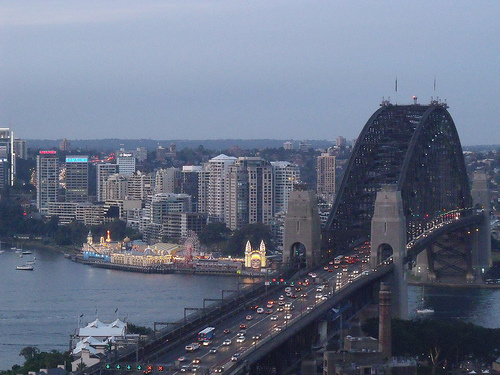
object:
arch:
[325, 95, 471, 262]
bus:
[197, 327, 215, 342]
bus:
[334, 255, 343, 264]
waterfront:
[83, 229, 267, 270]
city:
[0, 0, 500, 375]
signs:
[40, 150, 89, 163]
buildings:
[10, 130, 278, 244]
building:
[245, 240, 267, 269]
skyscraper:
[224, 156, 275, 231]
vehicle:
[270, 314, 278, 320]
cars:
[177, 237, 371, 373]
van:
[283, 302, 294, 313]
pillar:
[370, 187, 408, 277]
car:
[209, 348, 217, 352]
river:
[0, 245, 498, 373]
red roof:
[39, 150, 56, 154]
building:
[35, 150, 61, 210]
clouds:
[0, 0, 500, 146]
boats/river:
[0, 247, 38, 270]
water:
[18, 274, 163, 309]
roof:
[211, 153, 238, 160]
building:
[198, 153, 236, 236]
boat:
[416, 308, 434, 313]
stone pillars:
[369, 185, 408, 262]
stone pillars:
[283, 182, 322, 266]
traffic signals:
[109, 363, 165, 364]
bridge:
[79, 102, 487, 370]